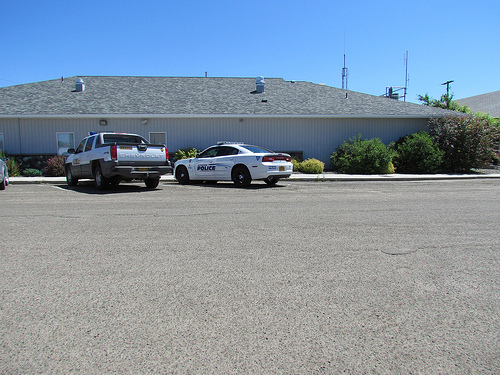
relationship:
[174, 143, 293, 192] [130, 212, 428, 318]
car in lot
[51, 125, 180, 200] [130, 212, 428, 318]
truck in lot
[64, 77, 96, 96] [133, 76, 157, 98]
vent on roof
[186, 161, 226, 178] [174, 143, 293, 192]
logo on car